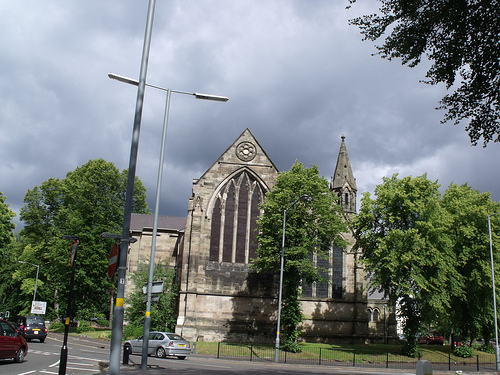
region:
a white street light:
[192, 85, 234, 108]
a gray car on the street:
[115, 325, 197, 363]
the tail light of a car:
[167, 337, 177, 346]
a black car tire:
[151, 345, 169, 359]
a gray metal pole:
[266, 209, 293, 367]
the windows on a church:
[204, 167, 269, 265]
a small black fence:
[213, 340, 497, 365]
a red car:
[0, 315, 33, 363]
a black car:
[3, 309, 49, 345]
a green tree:
[246, 151, 346, 351]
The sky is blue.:
[6, 3, 492, 203]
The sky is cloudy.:
[2, 0, 496, 208]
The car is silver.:
[120, 320, 195, 360]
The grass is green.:
[299, 325, 471, 367]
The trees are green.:
[357, 165, 497, 325]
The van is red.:
[0, 307, 27, 366]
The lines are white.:
[25, 338, 105, 373]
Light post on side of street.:
[103, 61, 239, 369]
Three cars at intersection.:
[1, 288, 188, 364]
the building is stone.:
[120, 92, 400, 349]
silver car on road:
[124, 328, 194, 363]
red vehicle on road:
[0, 326, 32, 363]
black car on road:
[20, 313, 47, 343]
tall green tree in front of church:
[258, 174, 322, 352]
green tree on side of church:
[42, 168, 109, 331]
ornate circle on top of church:
[234, 141, 257, 167]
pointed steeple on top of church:
[313, 130, 360, 218]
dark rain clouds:
[213, 32, 354, 152]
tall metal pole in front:
[278, 197, 288, 361]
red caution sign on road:
[104, 245, 114, 281]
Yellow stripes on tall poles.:
[100, 295, 174, 340]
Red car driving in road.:
[12, 322, 38, 356]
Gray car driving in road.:
[123, 317, 225, 373]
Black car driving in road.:
[20, 302, 91, 374]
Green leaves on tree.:
[40, 185, 138, 326]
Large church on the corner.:
[158, 130, 423, 370]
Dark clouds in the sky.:
[268, 97, 499, 146]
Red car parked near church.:
[423, 322, 455, 357]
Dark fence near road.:
[195, 340, 402, 373]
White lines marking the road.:
[35, 340, 90, 371]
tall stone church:
[124, 116, 461, 353]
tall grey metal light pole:
[100, 31, 164, 373]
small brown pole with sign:
[40, 236, 93, 373]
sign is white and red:
[60, 236, 85, 267]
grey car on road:
[120, 321, 192, 364]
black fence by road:
[183, 331, 448, 366]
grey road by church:
[185, 344, 362, 372]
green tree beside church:
[349, 167, 484, 361]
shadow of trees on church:
[315, 257, 402, 338]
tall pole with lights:
[97, 65, 183, 372]